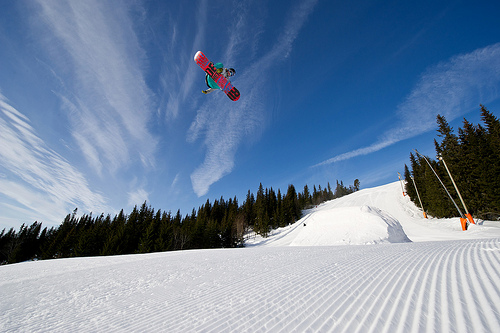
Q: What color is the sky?
A: Blue.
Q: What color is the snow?
A: White.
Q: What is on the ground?
A: Snow.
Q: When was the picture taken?
A: Daytime.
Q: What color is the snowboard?
A: Red and black.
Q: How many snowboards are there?
A: One.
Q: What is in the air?
A: The snowboard.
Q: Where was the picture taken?
A: Mountain.